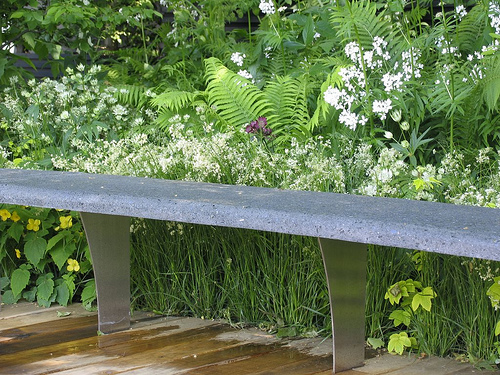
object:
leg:
[76, 212, 133, 339]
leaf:
[21, 30, 39, 50]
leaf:
[385, 307, 414, 329]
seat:
[0, 168, 500, 375]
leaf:
[200, 54, 290, 157]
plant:
[203, 56, 280, 149]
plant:
[383, 108, 436, 170]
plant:
[244, 115, 271, 148]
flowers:
[64, 256, 81, 272]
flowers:
[58, 212, 72, 229]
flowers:
[21, 216, 42, 232]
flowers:
[0, 209, 11, 224]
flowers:
[13, 246, 22, 258]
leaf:
[46, 233, 77, 271]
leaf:
[302, 8, 314, 47]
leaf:
[49, 238, 76, 269]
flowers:
[334, 108, 359, 130]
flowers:
[25, 216, 42, 233]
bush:
[49, 113, 500, 369]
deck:
[0, 300, 500, 375]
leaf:
[384, 328, 412, 358]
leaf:
[23, 234, 49, 269]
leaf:
[273, 72, 284, 79]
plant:
[433, 146, 499, 365]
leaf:
[209, 102, 239, 116]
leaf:
[5, 264, 32, 298]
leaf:
[411, 285, 438, 312]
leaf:
[7, 222, 27, 244]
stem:
[258, 125, 262, 140]